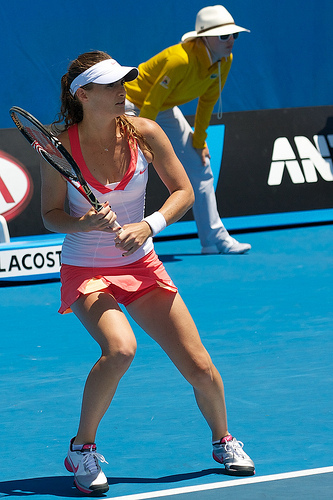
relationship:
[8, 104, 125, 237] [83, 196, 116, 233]
racket in hand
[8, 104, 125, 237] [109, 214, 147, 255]
racket in hand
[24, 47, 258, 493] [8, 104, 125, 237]
player holds racket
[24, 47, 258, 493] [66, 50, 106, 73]
player has hair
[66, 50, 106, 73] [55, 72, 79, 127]
hair in ponytail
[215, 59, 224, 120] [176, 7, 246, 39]
string on hat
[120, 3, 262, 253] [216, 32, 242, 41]
person wears sunglasses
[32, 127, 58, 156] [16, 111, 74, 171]
w on net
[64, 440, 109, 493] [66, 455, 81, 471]
sneaker has sign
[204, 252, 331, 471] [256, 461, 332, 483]
tennis court has line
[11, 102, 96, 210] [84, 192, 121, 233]
racket in hand